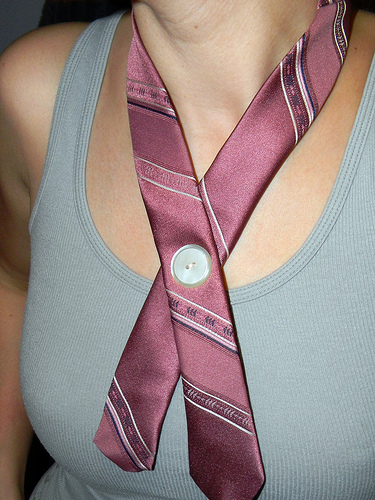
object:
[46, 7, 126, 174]
strap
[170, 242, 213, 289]
button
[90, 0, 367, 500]
tie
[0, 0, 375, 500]
woman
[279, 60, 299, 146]
stripes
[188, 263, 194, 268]
thread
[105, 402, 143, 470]
blue stripe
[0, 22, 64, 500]
arm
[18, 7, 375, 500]
shirt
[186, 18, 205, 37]
freckle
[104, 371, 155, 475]
stripe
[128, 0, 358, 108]
neck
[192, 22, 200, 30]
freckle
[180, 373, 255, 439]
stripe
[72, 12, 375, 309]
stitching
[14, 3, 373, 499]
tank top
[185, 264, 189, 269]
hole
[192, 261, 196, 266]
hole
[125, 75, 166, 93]
stripe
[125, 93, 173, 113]
stripe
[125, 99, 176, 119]
stripe